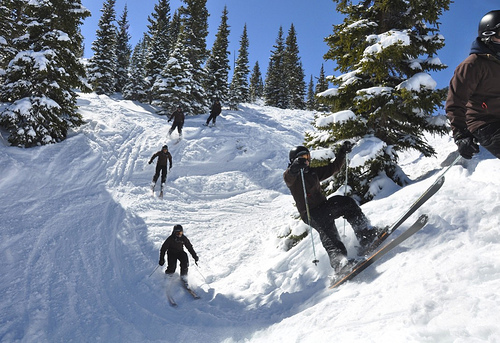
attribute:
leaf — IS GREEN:
[337, 40, 354, 54]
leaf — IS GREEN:
[306, 64, 441, 129]